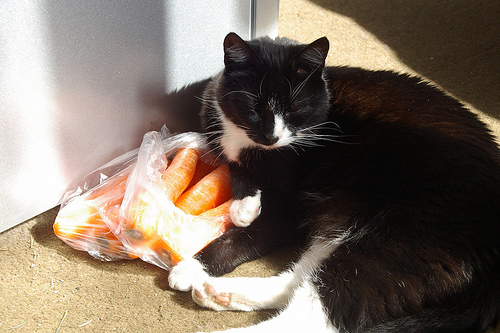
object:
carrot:
[54, 161, 132, 236]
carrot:
[127, 133, 200, 244]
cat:
[166, 33, 497, 332]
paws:
[230, 198, 265, 227]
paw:
[169, 255, 207, 295]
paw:
[191, 277, 234, 310]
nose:
[264, 133, 278, 144]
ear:
[220, 30, 263, 68]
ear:
[293, 36, 330, 73]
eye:
[240, 99, 259, 113]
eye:
[284, 103, 306, 116]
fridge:
[1, 1, 279, 233]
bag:
[52, 124, 248, 271]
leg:
[191, 245, 337, 311]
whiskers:
[198, 121, 251, 161]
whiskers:
[292, 120, 341, 143]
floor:
[1, 1, 498, 332]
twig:
[53, 307, 74, 332]